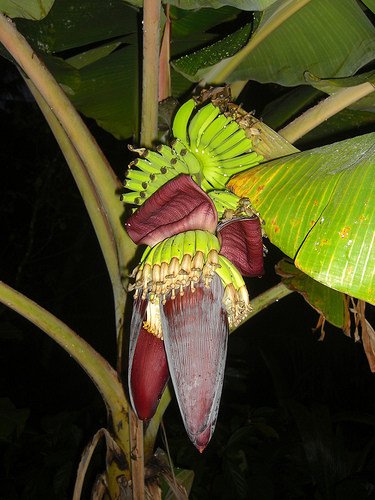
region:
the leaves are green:
[253, 158, 351, 276]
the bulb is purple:
[166, 290, 222, 458]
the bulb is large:
[162, 291, 231, 456]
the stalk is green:
[107, 388, 157, 487]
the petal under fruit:
[124, 174, 263, 272]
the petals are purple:
[142, 188, 266, 266]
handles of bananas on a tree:
[4, 84, 346, 457]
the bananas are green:
[106, 94, 263, 224]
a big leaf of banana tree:
[230, 126, 373, 323]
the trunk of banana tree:
[4, 282, 174, 499]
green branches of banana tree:
[2, 17, 168, 453]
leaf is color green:
[171, 2, 373, 98]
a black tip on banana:
[163, 134, 185, 152]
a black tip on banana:
[177, 147, 200, 171]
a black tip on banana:
[140, 147, 163, 166]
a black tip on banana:
[116, 188, 149, 205]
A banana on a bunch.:
[205, 233, 220, 269]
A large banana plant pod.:
[157, 272, 230, 454]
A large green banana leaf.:
[225, 132, 374, 313]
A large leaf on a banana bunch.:
[0, 17, 136, 379]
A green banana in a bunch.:
[170, 91, 200, 144]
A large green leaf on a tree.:
[169, 3, 372, 86]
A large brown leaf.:
[2, 282, 133, 468]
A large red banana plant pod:
[124, 174, 216, 246]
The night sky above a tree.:
[0, 37, 121, 374]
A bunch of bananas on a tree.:
[128, 222, 220, 302]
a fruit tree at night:
[84, 90, 320, 470]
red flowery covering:
[148, 255, 262, 475]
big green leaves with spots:
[236, 115, 373, 322]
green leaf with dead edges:
[272, 240, 373, 405]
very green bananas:
[106, 75, 268, 234]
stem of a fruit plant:
[36, 266, 209, 498]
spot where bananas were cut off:
[121, 224, 257, 349]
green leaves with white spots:
[171, 3, 309, 120]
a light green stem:
[274, 37, 370, 185]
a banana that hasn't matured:
[220, 253, 249, 306]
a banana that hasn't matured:
[211, 257, 231, 292]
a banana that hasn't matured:
[206, 225, 218, 267]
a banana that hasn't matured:
[179, 226, 195, 266]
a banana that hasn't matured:
[194, 227, 205, 278]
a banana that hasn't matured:
[154, 242, 163, 273]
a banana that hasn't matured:
[162, 235, 178, 277]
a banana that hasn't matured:
[212, 181, 247, 204]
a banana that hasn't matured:
[172, 90, 207, 155]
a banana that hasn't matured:
[196, 92, 216, 137]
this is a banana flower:
[118, 249, 266, 464]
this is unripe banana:
[175, 148, 208, 199]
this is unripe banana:
[168, 91, 196, 145]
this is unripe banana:
[190, 89, 217, 147]